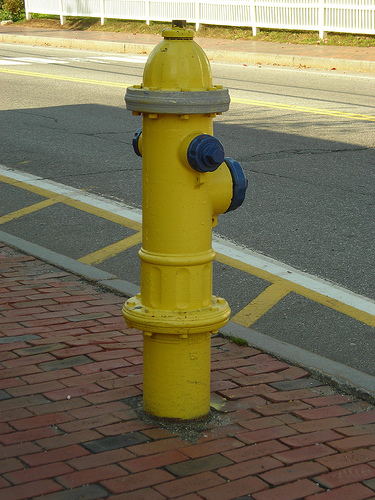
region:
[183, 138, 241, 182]
Blue nozzle on fire hydrant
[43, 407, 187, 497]
Weathered cobblestone sidewalk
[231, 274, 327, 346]
Yellow no parking lines on street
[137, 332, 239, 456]
Eroded base of fire hydrant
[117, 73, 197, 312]
Yellow fire hydrant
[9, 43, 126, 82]
White pedestrian crossing lines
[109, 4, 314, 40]
White wooden picket fence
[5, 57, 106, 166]
Empty asphalt street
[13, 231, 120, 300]
Concrete curb of road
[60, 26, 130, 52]
Brick sidewalk on opposite side of street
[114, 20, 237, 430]
Yellow fire hydrant with blue caps.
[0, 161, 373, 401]
Yellow lines next to road curb.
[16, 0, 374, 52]
White wooden fence next to a road.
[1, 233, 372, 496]
Red brick sidewalk.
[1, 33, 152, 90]
White crosswalk stripes.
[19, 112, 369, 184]
Cracks in paved road.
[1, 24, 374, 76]
Long brick sidewalk next to a road.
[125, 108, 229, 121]
Metal bolts on a fire hydrant.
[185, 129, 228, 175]
Metal blue cap.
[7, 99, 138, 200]
Shadow of a building.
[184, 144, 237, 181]
The plug on the side of the hydrant is blue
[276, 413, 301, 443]
The color of the brick on the sidewalk is red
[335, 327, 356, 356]
The color of the asphalt is black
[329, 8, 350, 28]
There is a white picket fence in the distance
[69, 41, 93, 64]
There is a grey curb on the other side of the street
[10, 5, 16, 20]
There is a green bush on the side of the white fence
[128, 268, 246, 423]
The base of the fire hydrant is yellow in color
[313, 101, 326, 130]
There is a yellow dividing line in the road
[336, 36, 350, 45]
There is green grass beneath the white fence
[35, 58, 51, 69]
There are white marks on the black asphalt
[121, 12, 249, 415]
a tall yellow and blue fire hydrant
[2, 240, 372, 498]
the sidewalk by the side of the road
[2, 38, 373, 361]
the street for cars to drive on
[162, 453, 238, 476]
a dark brink on the street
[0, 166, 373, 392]
the white and yellow lines on the road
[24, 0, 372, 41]
the fence on the other side of the road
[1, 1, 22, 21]
the green bush next to the fence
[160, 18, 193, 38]
the top of the hydrant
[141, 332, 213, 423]
the bottom of the hydrant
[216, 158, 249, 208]
the front of the hydrant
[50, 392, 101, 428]
white spot on ground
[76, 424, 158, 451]
black brick on ground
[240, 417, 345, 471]
cluster of red bricks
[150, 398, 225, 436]
rust at base of yellow hydrant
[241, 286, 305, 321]
wide yellow line on ground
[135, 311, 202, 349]
screws in yellow fire hydrant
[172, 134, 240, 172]
blue lid on yellow hydrant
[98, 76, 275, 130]
gray base on the hydrant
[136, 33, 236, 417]
large yellow fire hydrant on the side walk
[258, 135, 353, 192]
lines in the gray street